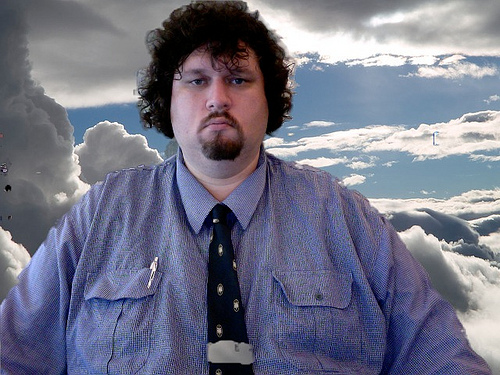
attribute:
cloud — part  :
[8, 5, 481, 318]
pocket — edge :
[266, 268, 364, 360]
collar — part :
[164, 147, 273, 231]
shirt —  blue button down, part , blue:
[10, 144, 484, 366]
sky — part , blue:
[7, 8, 482, 286]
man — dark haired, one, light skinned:
[5, 8, 481, 368]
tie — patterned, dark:
[200, 206, 255, 366]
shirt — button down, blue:
[4, 168, 484, 368]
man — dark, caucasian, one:
[1, 21, 450, 355]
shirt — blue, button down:
[9, 165, 451, 359]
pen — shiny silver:
[139, 243, 166, 291]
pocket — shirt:
[69, 265, 168, 364]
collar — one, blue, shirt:
[173, 153, 282, 233]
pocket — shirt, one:
[272, 267, 359, 365]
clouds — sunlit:
[328, 103, 449, 156]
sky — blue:
[317, 29, 482, 149]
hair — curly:
[139, 10, 302, 121]